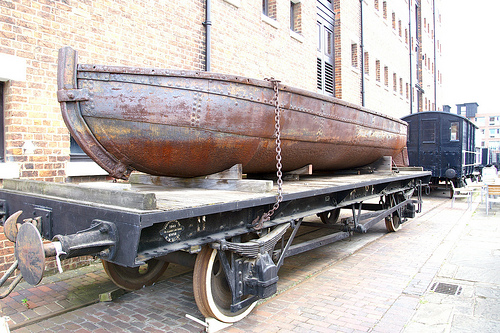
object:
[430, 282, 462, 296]
drain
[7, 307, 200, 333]
brick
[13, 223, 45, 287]
disk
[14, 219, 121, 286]
hitch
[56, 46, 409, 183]
boat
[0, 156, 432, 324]
cart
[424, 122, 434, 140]
windows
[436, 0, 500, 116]
white sky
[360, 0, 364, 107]
drain pipe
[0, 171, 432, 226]
flatbed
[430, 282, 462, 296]
sewer cover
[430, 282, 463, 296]
vent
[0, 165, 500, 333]
sidewalk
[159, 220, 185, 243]
sticker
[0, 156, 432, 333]
platform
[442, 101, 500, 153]
building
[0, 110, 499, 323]
train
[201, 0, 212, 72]
pipe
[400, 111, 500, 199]
car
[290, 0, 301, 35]
window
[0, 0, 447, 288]
building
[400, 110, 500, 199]
black engine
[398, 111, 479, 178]
train car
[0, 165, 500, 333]
floor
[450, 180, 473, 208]
chair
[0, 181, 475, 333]
track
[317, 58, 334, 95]
window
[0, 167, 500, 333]
red brick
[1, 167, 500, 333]
pavement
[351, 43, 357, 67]
window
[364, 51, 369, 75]
window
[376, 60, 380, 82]
window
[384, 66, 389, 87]
window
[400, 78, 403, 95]
window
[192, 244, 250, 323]
wheel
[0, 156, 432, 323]
trailer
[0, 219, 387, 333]
shadow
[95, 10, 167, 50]
wall